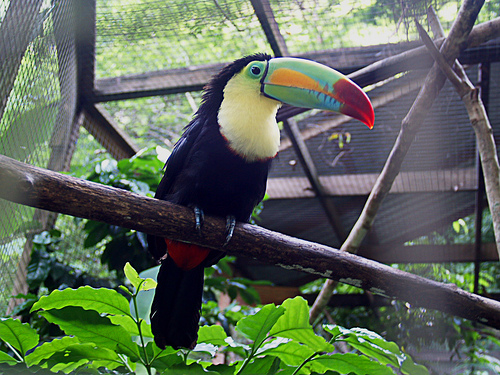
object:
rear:
[116, 182, 258, 282]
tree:
[18, 168, 337, 368]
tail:
[143, 240, 211, 352]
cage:
[1, 0, 500, 375]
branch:
[386, 0, 500, 177]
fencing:
[63, 40, 450, 276]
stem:
[130, 293, 145, 369]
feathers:
[139, 51, 283, 354]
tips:
[121, 210, 175, 330]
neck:
[207, 87, 275, 144]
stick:
[0, 150, 499, 330]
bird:
[152, 41, 343, 308]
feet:
[181, 201, 217, 238]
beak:
[260, 50, 379, 133]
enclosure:
[9, 3, 186, 107]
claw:
[190, 207, 207, 241]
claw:
[222, 214, 241, 245]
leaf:
[33, 285, 135, 320]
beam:
[70, 24, 117, 118]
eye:
[247, 62, 263, 78]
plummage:
[193, 157, 263, 207]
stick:
[411, 45, 499, 248]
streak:
[266, 60, 328, 99]